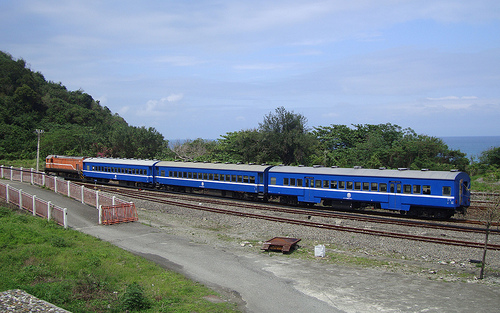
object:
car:
[44, 154, 86, 181]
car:
[83, 156, 160, 190]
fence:
[0, 166, 138, 228]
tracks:
[70, 177, 499, 250]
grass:
[0, 203, 234, 311]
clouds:
[402, 89, 490, 119]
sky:
[1, 1, 499, 135]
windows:
[282, 176, 403, 193]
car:
[267, 163, 471, 222]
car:
[153, 158, 270, 205]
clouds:
[122, 92, 194, 124]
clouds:
[37, 7, 312, 46]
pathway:
[90, 223, 342, 310]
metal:
[263, 235, 301, 252]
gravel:
[132, 198, 498, 263]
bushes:
[49, 100, 93, 127]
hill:
[0, 53, 168, 158]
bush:
[174, 137, 210, 161]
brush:
[372, 144, 423, 167]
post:
[63, 206, 68, 229]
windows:
[169, 169, 257, 184]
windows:
[91, 165, 149, 176]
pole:
[34, 126, 41, 171]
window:
[442, 186, 451, 195]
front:
[453, 171, 469, 212]